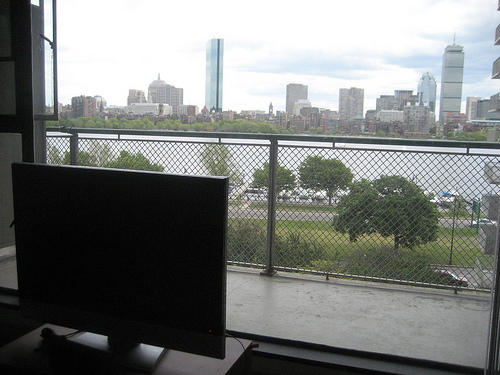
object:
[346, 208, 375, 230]
leaves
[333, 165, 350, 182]
leaves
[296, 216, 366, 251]
lawns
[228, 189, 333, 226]
roads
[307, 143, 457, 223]
water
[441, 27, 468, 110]
building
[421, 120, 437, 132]
houses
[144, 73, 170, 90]
house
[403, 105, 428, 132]
buildings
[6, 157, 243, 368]
screen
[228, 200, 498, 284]
grass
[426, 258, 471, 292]
car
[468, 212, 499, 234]
car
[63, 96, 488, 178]
tree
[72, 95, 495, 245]
river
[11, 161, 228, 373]
tv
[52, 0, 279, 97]
patch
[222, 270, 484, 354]
floor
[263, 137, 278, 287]
pole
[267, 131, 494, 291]
chain fence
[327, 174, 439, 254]
tree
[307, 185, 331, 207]
boat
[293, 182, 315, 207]
boat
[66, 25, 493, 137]
buildings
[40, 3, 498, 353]
window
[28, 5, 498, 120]
sky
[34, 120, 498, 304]
fence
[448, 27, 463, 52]
pole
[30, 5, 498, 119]
clouds